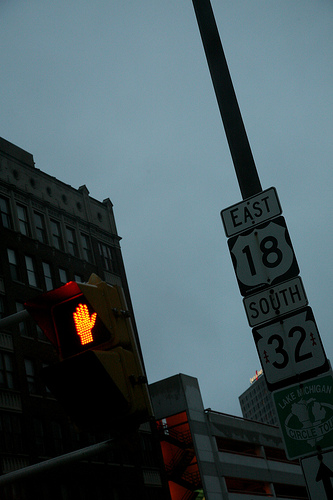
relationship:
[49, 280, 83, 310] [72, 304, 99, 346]
reflection of hand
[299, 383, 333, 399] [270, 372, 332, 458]
word on sign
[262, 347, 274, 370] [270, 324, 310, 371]
arrow pointing further 32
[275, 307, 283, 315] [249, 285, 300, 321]
bolt holding down word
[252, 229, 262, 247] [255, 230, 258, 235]
stain from bolt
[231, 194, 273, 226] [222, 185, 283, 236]
east in rectangle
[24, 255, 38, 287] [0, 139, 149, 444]
window in building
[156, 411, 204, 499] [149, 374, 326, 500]
stairs in a building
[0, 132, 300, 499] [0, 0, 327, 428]
building in distance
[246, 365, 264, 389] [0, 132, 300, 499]
sign on building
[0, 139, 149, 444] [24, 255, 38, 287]
building with window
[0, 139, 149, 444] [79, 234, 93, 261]
building with window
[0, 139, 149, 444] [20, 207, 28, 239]
building with window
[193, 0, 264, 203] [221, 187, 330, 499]
post with sign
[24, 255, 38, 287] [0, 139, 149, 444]
window on building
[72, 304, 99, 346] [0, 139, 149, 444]
light on building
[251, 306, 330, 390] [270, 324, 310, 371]
sign with number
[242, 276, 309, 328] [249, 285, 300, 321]
sign reads south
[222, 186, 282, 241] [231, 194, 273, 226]
sign reads east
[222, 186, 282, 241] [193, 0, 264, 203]
sign affixed to post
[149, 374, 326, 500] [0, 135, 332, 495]
garage in background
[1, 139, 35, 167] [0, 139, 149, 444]
top of building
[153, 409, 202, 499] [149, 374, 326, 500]
light in garage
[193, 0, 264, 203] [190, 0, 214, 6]
post for lamp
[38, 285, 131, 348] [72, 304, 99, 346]
sign says don't cross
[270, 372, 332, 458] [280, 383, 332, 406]
sign about lake michigan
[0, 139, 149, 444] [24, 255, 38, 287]
building has window